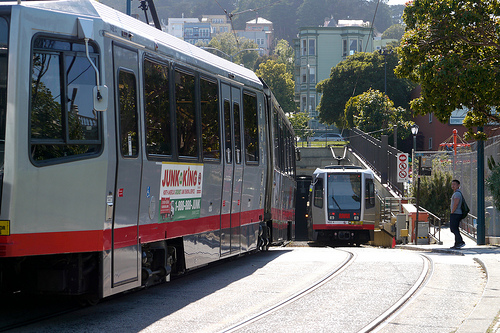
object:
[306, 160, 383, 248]
train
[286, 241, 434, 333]
tracks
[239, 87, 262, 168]
windows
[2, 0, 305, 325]
train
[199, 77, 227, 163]
windows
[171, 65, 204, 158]
windows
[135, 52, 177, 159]
windows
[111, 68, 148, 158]
windows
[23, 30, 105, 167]
windows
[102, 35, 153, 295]
door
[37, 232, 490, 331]
road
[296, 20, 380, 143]
buildings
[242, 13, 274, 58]
buildings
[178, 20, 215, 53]
buildings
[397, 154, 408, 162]
signs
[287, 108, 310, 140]
trees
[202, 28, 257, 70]
trees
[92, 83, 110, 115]
mirror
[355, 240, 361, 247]
wheel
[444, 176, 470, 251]
man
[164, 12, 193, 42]
buildings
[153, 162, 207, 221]
advertisement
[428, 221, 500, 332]
sidewalk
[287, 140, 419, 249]
tunnel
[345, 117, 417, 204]
fence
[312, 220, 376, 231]
stripe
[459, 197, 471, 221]
backpack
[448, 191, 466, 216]
shirt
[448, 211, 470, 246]
pants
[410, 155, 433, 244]
post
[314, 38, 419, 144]
tree